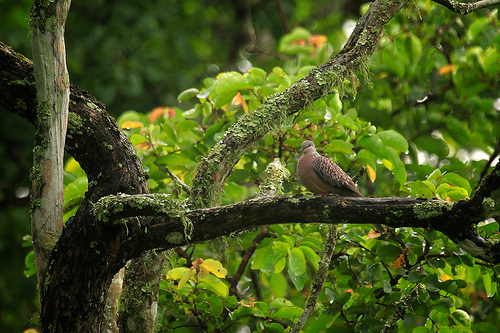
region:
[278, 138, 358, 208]
a bird on a branch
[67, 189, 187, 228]
green stuff growing on a tree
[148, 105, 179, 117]
a red leaf on a tree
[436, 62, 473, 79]
a orange leaf on a tree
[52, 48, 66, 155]
a grey tree trunk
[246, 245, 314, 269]
a bunch of green leaves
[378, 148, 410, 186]
green leaf on tree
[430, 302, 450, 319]
green leaf on tree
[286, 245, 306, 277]
green leaf on tree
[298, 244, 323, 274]
green leaf on tree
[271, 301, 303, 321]
green leaf on tree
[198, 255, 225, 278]
green leaf on tree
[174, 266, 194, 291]
green leaf on tree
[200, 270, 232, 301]
green leaf on tree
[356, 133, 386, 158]
green leaf on tree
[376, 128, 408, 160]
green leaf on tree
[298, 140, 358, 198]
Gray bird sitting on branch.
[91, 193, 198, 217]
Green bird nest built in tree gap.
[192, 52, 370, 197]
Bird sitting under moss covered branch.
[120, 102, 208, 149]
Several orange and yellow leaves beside green ones.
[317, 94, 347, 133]
Drop of water on green leaf.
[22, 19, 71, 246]
Dried out tree trunk.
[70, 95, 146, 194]
Curved black tree trunk.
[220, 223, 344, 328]
Couple of thin gray branches under the bird.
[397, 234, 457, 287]
Leaves with several water droplets.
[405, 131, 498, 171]
White area in gap between leaves.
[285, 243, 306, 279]
green leaf by the pretty bird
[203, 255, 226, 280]
green leaf by the pretty bird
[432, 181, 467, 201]
green leaf by the pretty bird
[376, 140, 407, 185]
green leaf by the pretty bird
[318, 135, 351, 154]
green leaf by the pretty bird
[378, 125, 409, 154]
green leaf by the pretty bird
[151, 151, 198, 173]
green leaf by the pretty bird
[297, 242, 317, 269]
green leaf by the pretty bird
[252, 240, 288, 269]
green leaf by the pretty bird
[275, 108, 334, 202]
bird on tree branch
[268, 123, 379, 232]
bird on tree branch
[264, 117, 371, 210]
bird on tree branch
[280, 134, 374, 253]
bird on tree branch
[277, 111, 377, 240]
bird on tree branch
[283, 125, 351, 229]
the bird is brown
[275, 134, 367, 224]
the bird is brown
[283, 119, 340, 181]
the bird is brown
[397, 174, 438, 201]
green leaf by the pretty bird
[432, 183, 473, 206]
green leaf by the pretty bird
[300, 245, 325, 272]
green leaf by the pretty bird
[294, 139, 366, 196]
brown dove perched on branch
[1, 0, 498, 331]
tree with moss covered branches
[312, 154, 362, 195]
brown dove's left wing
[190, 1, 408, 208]
horizontal branch covered in moss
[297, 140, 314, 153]
dove's small head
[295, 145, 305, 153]
dove's tiny beak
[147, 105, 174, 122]
bright reddish-orange leaf on tree